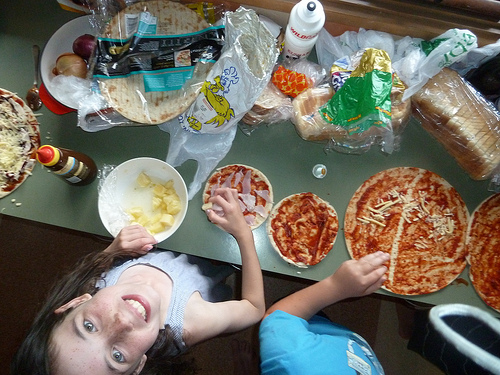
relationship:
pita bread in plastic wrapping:
[80, 0, 221, 121] [74, 2, 233, 127]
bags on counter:
[56, 6, 494, 198] [0, 4, 499, 320]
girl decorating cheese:
[14, 185, 264, 372] [265, 189, 339, 267]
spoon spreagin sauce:
[21, 65, 42, 116] [375, 187, 447, 267]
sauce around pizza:
[375, 187, 447, 267] [343, 164, 471, 296]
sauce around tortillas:
[375, 187, 447, 267] [276, 189, 335, 269]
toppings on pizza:
[224, 173, 256, 211] [204, 162, 273, 232]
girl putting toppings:
[14, 185, 264, 372] [224, 173, 256, 211]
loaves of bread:
[403, 63, 498, 176] [413, 69, 498, 180]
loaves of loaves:
[279, 76, 409, 119] [290, 70, 411, 143]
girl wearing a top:
[14, 185, 264, 372] [93, 250, 233, 350]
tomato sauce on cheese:
[269, 187, 335, 266] [265, 189, 339, 267]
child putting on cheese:
[256, 250, 392, 374] [263, 156, 330, 281]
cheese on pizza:
[263, 156, 330, 281] [361, 115, 426, 302]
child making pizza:
[241, 252, 415, 374] [343, 164, 469, 296]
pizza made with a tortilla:
[343, 164, 469, 296] [97, 0, 210, 125]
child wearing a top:
[241, 252, 415, 374] [260, 311, 388, 373]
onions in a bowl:
[60, 41, 107, 86] [42, 16, 130, 128]